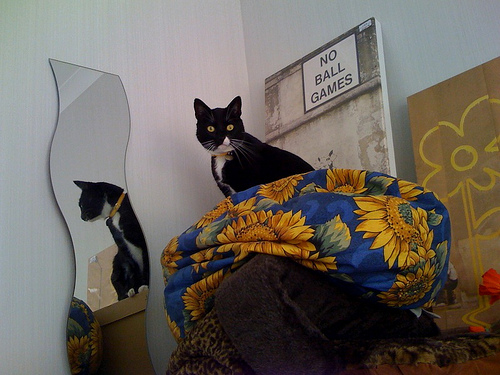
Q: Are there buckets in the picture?
A: No, there are no buckets.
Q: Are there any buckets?
A: No, there are no buckets.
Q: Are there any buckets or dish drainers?
A: No, there are no buckets or dish drainers.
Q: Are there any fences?
A: No, there are no fences.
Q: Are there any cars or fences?
A: No, there are no fences or cars.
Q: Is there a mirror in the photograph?
A: Yes, there is a mirror.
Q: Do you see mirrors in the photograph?
A: Yes, there is a mirror.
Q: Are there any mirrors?
A: Yes, there is a mirror.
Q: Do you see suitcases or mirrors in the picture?
A: Yes, there is a mirror.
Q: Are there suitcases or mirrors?
A: Yes, there is a mirror.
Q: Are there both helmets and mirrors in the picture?
A: No, there is a mirror but no helmets.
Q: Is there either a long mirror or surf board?
A: Yes, there is a long mirror.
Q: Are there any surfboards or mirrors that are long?
A: Yes, the mirror is long.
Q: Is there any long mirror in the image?
A: Yes, there is a long mirror.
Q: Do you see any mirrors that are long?
A: Yes, there is a mirror that is long.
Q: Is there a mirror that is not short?
A: Yes, there is a long mirror.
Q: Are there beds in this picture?
A: No, there are no beds.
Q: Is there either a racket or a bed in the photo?
A: No, there are no beds or rackets.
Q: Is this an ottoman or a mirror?
A: This is a mirror.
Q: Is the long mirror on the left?
A: Yes, the mirror is on the left of the image.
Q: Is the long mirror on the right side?
A: No, the mirror is on the left of the image.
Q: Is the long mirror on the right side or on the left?
A: The mirror is on the left of the image.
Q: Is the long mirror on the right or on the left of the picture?
A: The mirror is on the left of the image.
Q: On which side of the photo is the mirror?
A: The mirror is on the left of the image.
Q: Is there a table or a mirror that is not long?
A: No, there is a mirror but it is long.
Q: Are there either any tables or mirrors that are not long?
A: No, there is a mirror but it is long.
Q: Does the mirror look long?
A: Yes, the mirror is long.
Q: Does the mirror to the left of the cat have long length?
A: Yes, the mirror is long.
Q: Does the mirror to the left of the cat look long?
A: Yes, the mirror is long.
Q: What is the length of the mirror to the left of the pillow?
A: The mirror is long.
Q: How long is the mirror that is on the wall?
A: The mirror is long.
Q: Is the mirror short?
A: No, the mirror is long.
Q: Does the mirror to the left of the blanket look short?
A: No, the mirror is long.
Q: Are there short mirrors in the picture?
A: No, there is a mirror but it is long.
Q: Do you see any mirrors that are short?
A: No, there is a mirror but it is long.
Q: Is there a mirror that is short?
A: No, there is a mirror but it is long.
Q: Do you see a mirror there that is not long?
A: No, there is a mirror but it is long.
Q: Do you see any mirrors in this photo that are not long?
A: No, there is a mirror but it is long.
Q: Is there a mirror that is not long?
A: No, there is a mirror but it is long.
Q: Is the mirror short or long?
A: The mirror is long.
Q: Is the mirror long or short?
A: The mirror is long.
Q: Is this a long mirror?
A: Yes, this is a long mirror.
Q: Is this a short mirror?
A: No, this is a long mirror.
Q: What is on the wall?
A: The mirror is on the wall.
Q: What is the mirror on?
A: The mirror is on the wall.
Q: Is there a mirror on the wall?
A: Yes, there is a mirror on the wall.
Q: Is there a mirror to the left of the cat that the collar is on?
A: Yes, there is a mirror to the left of the cat.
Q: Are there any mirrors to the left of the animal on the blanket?
A: Yes, there is a mirror to the left of the cat.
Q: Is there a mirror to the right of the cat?
A: No, the mirror is to the left of the cat.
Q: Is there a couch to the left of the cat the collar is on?
A: No, there is a mirror to the left of the cat.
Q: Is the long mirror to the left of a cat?
A: Yes, the mirror is to the left of a cat.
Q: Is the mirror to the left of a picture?
A: No, the mirror is to the left of a cat.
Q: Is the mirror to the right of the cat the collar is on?
A: No, the mirror is to the left of the cat.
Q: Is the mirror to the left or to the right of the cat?
A: The mirror is to the left of the cat.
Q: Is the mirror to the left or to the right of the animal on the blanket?
A: The mirror is to the left of the cat.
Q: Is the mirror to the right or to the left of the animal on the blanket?
A: The mirror is to the left of the cat.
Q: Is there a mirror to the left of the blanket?
A: Yes, there is a mirror to the left of the blanket.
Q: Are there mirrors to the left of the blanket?
A: Yes, there is a mirror to the left of the blanket.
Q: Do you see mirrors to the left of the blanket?
A: Yes, there is a mirror to the left of the blanket.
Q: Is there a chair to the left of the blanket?
A: No, there is a mirror to the left of the blanket.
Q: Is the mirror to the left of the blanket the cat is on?
A: Yes, the mirror is to the left of the blanket.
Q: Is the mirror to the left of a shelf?
A: No, the mirror is to the left of the blanket.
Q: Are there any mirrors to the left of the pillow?
A: Yes, there is a mirror to the left of the pillow.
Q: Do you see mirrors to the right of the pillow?
A: No, the mirror is to the left of the pillow.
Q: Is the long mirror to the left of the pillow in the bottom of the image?
A: Yes, the mirror is to the left of the pillow.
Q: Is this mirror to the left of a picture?
A: No, the mirror is to the left of the pillow.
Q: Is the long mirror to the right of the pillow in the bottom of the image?
A: No, the mirror is to the left of the pillow.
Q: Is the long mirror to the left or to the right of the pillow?
A: The mirror is to the left of the pillow.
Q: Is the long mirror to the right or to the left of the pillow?
A: The mirror is to the left of the pillow.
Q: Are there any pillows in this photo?
A: Yes, there is a pillow.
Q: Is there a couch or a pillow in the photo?
A: Yes, there is a pillow.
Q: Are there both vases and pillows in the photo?
A: No, there is a pillow but no vases.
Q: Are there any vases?
A: No, there are no vases.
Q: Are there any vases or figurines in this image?
A: No, there are no vases or figurines.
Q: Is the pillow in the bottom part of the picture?
A: Yes, the pillow is in the bottom of the image.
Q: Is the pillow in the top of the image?
A: No, the pillow is in the bottom of the image.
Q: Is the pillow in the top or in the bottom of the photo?
A: The pillow is in the bottom of the image.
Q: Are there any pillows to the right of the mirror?
A: Yes, there is a pillow to the right of the mirror.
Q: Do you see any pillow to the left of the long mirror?
A: No, the pillow is to the right of the mirror.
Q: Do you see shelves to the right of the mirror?
A: No, there is a pillow to the right of the mirror.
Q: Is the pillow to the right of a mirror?
A: Yes, the pillow is to the right of a mirror.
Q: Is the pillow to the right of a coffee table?
A: No, the pillow is to the right of a mirror.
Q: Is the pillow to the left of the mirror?
A: No, the pillow is to the right of the mirror.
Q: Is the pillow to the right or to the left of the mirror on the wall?
A: The pillow is to the right of the mirror.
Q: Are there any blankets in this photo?
A: Yes, there is a blanket.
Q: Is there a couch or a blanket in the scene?
A: Yes, there is a blanket.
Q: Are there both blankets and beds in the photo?
A: No, there is a blanket but no beds.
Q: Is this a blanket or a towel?
A: This is a blanket.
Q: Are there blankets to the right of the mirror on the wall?
A: Yes, there is a blanket to the right of the mirror.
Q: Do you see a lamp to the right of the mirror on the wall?
A: No, there is a blanket to the right of the mirror.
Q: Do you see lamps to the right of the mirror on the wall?
A: No, there is a blanket to the right of the mirror.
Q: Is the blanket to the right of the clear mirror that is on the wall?
A: Yes, the blanket is to the right of the mirror.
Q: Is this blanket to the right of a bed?
A: No, the blanket is to the right of the mirror.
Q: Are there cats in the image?
A: Yes, there is a cat.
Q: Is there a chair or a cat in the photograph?
A: Yes, there is a cat.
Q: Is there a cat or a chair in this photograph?
A: Yes, there is a cat.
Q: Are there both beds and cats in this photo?
A: No, there is a cat but no beds.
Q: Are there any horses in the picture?
A: No, there are no horses.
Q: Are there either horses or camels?
A: No, there are no horses or camels.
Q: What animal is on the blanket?
A: The cat is on the blanket.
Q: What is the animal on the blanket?
A: The animal is a cat.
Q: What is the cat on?
A: The cat is on the blanket.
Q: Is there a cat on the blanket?
A: Yes, there is a cat on the blanket.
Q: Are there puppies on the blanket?
A: No, there is a cat on the blanket.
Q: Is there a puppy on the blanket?
A: No, there is a cat on the blanket.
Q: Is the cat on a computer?
A: No, the cat is on the blanket.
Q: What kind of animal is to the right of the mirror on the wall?
A: The animal is a cat.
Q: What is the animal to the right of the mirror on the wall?
A: The animal is a cat.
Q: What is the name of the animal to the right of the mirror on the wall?
A: The animal is a cat.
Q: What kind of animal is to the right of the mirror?
A: The animal is a cat.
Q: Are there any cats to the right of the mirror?
A: Yes, there is a cat to the right of the mirror.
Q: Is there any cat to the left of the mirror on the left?
A: No, the cat is to the right of the mirror.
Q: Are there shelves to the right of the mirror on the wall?
A: No, there is a cat to the right of the mirror.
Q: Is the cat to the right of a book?
A: No, the cat is to the right of the mirror.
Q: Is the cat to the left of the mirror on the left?
A: No, the cat is to the right of the mirror.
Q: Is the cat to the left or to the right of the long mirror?
A: The cat is to the right of the mirror.